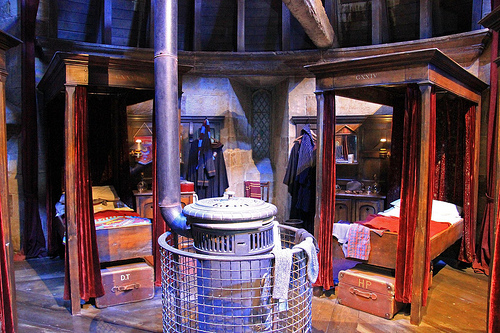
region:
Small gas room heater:
[160, 172, 305, 327]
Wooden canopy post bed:
[305, 50, 480, 275]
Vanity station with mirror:
[295, 105, 385, 205]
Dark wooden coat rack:
[180, 105, 230, 190]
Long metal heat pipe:
[146, 0, 191, 235]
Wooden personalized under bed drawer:
[330, 265, 401, 320]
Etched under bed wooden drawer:
[91, 266, 152, 307]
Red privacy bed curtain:
[390, 86, 437, 306]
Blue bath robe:
[295, 125, 311, 222]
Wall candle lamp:
[130, 132, 146, 162]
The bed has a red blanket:
[301, 55, 481, 307]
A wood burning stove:
[119, 188, 299, 331]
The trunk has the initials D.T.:
[91, 262, 168, 313]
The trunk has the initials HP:
[327, 263, 419, 328]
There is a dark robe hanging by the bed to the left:
[188, 120, 238, 222]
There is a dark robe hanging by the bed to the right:
[284, 127, 334, 238]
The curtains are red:
[383, 87, 435, 315]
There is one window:
[242, 85, 282, 173]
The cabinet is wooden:
[321, 188, 398, 258]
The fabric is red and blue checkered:
[336, 221, 380, 269]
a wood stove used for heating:
[152, 1, 316, 332]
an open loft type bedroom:
[1, 0, 497, 332]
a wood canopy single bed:
[302, 47, 489, 325]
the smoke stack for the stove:
[151, 1, 190, 232]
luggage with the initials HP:
[335, 264, 397, 318]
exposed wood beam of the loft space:
[285, 1, 339, 49]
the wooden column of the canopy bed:
[408, 81, 431, 326]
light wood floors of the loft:
[429, 263, 491, 332]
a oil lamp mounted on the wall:
[377, 123, 390, 162]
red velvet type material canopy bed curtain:
[392, 81, 419, 304]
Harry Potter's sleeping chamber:
[31, 13, 481, 318]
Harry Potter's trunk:
[330, 272, 402, 316]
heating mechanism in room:
[163, 184, 318, 319]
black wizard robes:
[277, 115, 322, 220]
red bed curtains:
[382, 78, 453, 315]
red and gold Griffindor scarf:
[234, 176, 266, 208]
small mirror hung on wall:
[332, 128, 363, 171]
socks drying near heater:
[256, 233, 326, 313]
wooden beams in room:
[265, 0, 343, 59]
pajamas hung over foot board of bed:
[330, 218, 387, 268]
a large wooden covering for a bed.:
[301, 44, 481, 325]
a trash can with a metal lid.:
[176, 179, 286, 328]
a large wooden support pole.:
[143, 0, 193, 317]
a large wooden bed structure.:
[46, 36, 328, 327]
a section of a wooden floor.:
[441, 285, 474, 327]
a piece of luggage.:
[92, 259, 154, 321]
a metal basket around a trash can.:
[151, 199, 317, 331]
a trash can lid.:
[177, 188, 279, 231]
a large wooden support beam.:
[272, 0, 342, 55]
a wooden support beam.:
[86, 0, 133, 52]